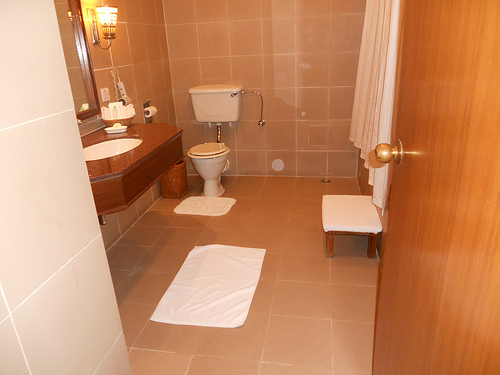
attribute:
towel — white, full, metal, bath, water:
[195, 256, 281, 341]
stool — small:
[315, 189, 383, 265]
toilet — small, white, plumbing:
[185, 132, 255, 223]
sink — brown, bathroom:
[94, 134, 162, 191]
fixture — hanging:
[81, 5, 133, 58]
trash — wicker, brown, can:
[138, 143, 199, 213]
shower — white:
[314, 18, 417, 195]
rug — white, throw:
[175, 196, 228, 219]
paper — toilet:
[141, 98, 158, 133]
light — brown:
[88, 7, 123, 53]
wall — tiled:
[124, 26, 163, 71]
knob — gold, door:
[365, 137, 398, 166]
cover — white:
[308, 192, 397, 246]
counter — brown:
[145, 125, 189, 180]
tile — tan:
[262, 179, 308, 210]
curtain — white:
[361, 22, 410, 89]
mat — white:
[173, 193, 246, 228]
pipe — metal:
[206, 119, 241, 143]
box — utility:
[110, 67, 142, 102]